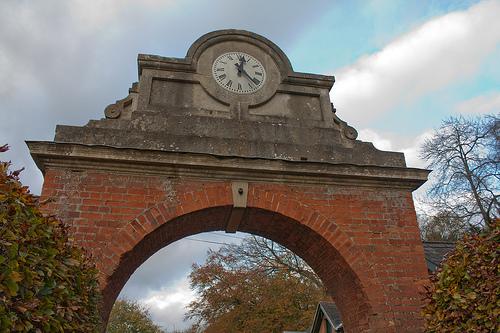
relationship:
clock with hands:
[211, 51, 267, 94] [234, 56, 259, 86]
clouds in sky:
[323, 1, 498, 224] [1, 0, 499, 332]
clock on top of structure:
[211, 51, 267, 94] [23, 28, 432, 333]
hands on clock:
[234, 56, 259, 86] [211, 51, 267, 94]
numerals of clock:
[217, 55, 262, 90] [211, 51, 267, 94]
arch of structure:
[39, 168, 433, 333] [23, 28, 432, 333]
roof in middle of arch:
[305, 302, 342, 333] [39, 168, 433, 333]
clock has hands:
[211, 51, 267, 94] [234, 56, 259, 86]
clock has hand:
[211, 51, 267, 94] [234, 63, 259, 86]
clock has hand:
[211, 51, 267, 94] [236, 55, 245, 78]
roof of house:
[305, 302, 342, 333] [309, 240, 460, 332]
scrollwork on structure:
[103, 81, 140, 120] [23, 28, 432, 333]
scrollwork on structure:
[330, 104, 362, 143] [23, 28, 432, 333]